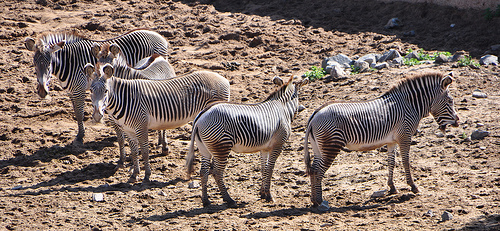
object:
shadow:
[0, 176, 194, 199]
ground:
[1, 1, 499, 228]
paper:
[90, 190, 105, 205]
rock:
[326, 64, 350, 82]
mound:
[245, 0, 500, 51]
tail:
[180, 125, 197, 178]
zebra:
[303, 71, 461, 210]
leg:
[397, 135, 423, 194]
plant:
[304, 65, 326, 81]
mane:
[384, 72, 446, 97]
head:
[429, 71, 461, 131]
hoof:
[410, 188, 422, 194]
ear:
[440, 75, 455, 90]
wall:
[420, 0, 498, 12]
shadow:
[0, 134, 132, 170]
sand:
[0, 0, 500, 228]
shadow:
[2, 161, 121, 192]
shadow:
[118, 200, 253, 225]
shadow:
[235, 193, 420, 220]